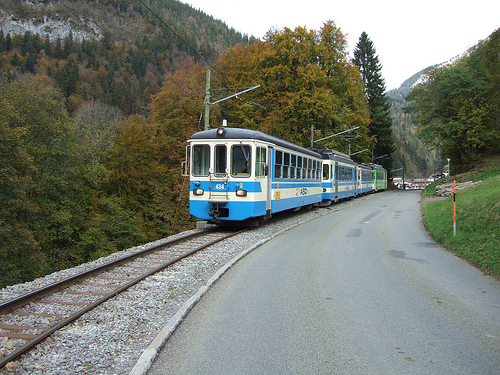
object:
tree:
[346, 30, 395, 190]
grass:
[487, 259, 498, 276]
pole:
[453, 180, 456, 236]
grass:
[474, 222, 483, 228]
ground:
[389, 241, 434, 271]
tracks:
[178, 232, 195, 242]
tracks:
[106, 286, 120, 298]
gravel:
[59, 346, 82, 362]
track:
[0, 353, 15, 374]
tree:
[3, 71, 73, 156]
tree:
[1, 225, 47, 281]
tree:
[101, 114, 169, 231]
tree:
[154, 52, 228, 232]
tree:
[317, 20, 369, 158]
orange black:
[454, 191, 457, 195]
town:
[386, 174, 449, 189]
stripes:
[249, 192, 262, 202]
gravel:
[186, 250, 204, 270]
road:
[168, 309, 499, 373]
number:
[215, 184, 224, 190]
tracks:
[2, 291, 31, 314]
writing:
[299, 187, 307, 195]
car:
[370, 163, 388, 192]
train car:
[181, 119, 324, 232]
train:
[179, 119, 389, 233]